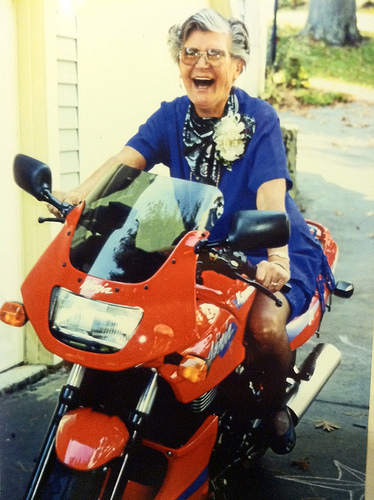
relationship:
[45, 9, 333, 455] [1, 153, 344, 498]
woman on motorcycle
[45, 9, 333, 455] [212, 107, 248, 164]
woman has corsage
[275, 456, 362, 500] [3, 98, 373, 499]
chalk on concrete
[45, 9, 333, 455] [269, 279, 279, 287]
woman has ring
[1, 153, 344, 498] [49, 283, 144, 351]
motorcycle has light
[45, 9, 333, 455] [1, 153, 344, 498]
woman rides motorcycle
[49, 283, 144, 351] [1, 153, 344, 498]
light on motorcycle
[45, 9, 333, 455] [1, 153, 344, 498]
woman riding motorcycle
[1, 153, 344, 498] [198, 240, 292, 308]
motorcycle has handlebars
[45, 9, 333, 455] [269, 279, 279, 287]
woman wears ring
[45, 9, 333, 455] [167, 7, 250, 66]
woman has hair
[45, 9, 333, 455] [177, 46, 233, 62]
woman wears glasses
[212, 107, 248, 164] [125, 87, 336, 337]
corsage on dress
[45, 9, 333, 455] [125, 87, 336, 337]
woman wears dress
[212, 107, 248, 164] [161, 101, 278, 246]
corsage on chest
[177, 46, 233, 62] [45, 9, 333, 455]
glasses on woman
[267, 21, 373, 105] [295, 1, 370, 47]
grass before trunk